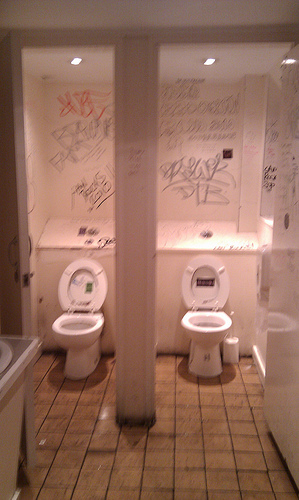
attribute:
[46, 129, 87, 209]
walls — white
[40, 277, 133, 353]
bowl — white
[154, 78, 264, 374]
bathroom stall — vacant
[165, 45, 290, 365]
stall — bathroom stall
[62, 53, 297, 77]
lights — bright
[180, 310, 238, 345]
seat — white, toilet seat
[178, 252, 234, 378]
toilet — clean, open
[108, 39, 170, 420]
ark — tall, thick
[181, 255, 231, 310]
toilet seat — up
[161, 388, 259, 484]
floor — tan, ceramic tile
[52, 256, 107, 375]
seat — up, toilet seat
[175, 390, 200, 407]
floor tile — dully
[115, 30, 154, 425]
placard — white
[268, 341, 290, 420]
side — white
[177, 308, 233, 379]
toilet bowl — clean